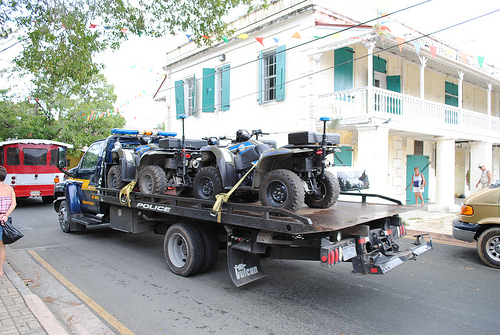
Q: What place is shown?
A: It is a road.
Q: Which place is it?
A: It is a road.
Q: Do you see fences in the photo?
A: No, there are no fences.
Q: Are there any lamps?
A: No, there are no lamps.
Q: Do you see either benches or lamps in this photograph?
A: No, there are no lamps or benches.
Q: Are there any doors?
A: Yes, there is a door.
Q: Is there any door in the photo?
A: Yes, there is a door.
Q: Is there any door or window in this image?
A: Yes, there is a door.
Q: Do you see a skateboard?
A: No, there are no skateboards.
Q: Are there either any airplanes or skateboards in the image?
A: No, there are no skateboards or airplanes.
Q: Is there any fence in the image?
A: No, there are no fences.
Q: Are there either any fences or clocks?
A: No, there are no fences or clocks.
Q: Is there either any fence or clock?
A: No, there are no fences or clocks.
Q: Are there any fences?
A: No, there are no fences.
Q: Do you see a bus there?
A: Yes, there is a bus.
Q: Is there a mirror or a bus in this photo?
A: Yes, there is a bus.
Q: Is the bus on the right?
A: No, the bus is on the left of the image.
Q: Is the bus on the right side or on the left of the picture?
A: The bus is on the left of the image.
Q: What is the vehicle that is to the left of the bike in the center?
A: The vehicle is a bus.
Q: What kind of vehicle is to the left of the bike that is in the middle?
A: The vehicle is a bus.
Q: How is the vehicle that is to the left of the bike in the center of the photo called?
A: The vehicle is a bus.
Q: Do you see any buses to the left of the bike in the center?
A: Yes, there is a bus to the left of the bike.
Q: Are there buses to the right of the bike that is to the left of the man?
A: No, the bus is to the left of the bike.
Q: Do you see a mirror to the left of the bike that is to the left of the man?
A: No, there is a bus to the left of the bike.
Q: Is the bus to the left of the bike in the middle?
A: Yes, the bus is to the left of the bike.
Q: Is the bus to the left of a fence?
A: No, the bus is to the left of the bike.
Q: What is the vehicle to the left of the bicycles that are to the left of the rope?
A: The vehicle is a bus.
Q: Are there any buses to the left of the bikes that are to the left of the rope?
A: Yes, there is a bus to the left of the bikes.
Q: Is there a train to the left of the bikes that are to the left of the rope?
A: No, there is a bus to the left of the bicycles.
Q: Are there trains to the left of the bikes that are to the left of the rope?
A: No, there is a bus to the left of the bicycles.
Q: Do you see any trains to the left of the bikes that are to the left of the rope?
A: No, there is a bus to the left of the bicycles.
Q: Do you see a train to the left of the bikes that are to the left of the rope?
A: No, there is a bus to the left of the bicycles.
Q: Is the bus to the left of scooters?
A: No, the bus is to the left of the bicycles.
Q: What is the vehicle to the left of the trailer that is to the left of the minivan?
A: The vehicle is a bus.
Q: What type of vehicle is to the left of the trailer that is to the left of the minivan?
A: The vehicle is a bus.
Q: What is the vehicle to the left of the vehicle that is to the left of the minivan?
A: The vehicle is a bus.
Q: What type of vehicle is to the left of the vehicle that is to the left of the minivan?
A: The vehicle is a bus.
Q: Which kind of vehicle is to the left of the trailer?
A: The vehicle is a bus.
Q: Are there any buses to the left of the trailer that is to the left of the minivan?
A: Yes, there is a bus to the left of the trailer.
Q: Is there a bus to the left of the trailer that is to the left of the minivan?
A: Yes, there is a bus to the left of the trailer.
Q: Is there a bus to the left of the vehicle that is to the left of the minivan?
A: Yes, there is a bus to the left of the trailer.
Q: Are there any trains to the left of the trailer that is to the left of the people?
A: No, there is a bus to the left of the trailer.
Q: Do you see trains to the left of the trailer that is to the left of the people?
A: No, there is a bus to the left of the trailer.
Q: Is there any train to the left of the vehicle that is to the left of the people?
A: No, there is a bus to the left of the trailer.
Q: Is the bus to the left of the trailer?
A: Yes, the bus is to the left of the trailer.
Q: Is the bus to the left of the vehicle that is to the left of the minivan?
A: Yes, the bus is to the left of the trailer.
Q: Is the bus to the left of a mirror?
A: No, the bus is to the left of the trailer.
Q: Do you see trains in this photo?
A: No, there are no trains.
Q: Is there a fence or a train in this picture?
A: No, there are no trains or fences.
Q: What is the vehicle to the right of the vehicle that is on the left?
A: The vehicle is a trailer.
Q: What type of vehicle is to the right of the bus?
A: The vehicle is a trailer.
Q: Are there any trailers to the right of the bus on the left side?
A: Yes, there is a trailer to the right of the bus.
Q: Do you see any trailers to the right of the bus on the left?
A: Yes, there is a trailer to the right of the bus.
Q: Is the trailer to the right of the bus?
A: Yes, the trailer is to the right of the bus.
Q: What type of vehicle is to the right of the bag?
A: The vehicle is a trailer.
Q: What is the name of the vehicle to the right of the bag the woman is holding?
A: The vehicle is a trailer.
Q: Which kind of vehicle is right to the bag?
A: The vehicle is a trailer.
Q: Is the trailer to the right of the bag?
A: Yes, the trailer is to the right of the bag.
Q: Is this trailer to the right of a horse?
A: No, the trailer is to the right of the bag.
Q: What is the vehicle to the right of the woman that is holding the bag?
A: The vehicle is a trailer.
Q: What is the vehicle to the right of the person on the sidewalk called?
A: The vehicle is a trailer.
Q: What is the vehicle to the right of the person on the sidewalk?
A: The vehicle is a trailer.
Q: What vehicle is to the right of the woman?
A: The vehicle is a trailer.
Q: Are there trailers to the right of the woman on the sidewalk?
A: Yes, there is a trailer to the right of the woman.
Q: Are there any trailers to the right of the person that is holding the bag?
A: Yes, there is a trailer to the right of the woman.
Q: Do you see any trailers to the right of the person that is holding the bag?
A: Yes, there is a trailer to the right of the woman.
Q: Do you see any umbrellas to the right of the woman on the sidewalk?
A: No, there is a trailer to the right of the woman.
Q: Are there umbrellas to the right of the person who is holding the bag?
A: No, there is a trailer to the right of the woman.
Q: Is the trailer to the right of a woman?
A: Yes, the trailer is to the right of a woman.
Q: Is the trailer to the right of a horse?
A: No, the trailer is to the right of a woman.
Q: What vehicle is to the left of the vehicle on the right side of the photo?
A: The vehicle is a trailer.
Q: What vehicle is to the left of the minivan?
A: The vehicle is a trailer.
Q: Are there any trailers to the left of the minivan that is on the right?
A: Yes, there is a trailer to the left of the minivan.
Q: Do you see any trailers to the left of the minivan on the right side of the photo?
A: Yes, there is a trailer to the left of the minivan.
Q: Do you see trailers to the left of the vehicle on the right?
A: Yes, there is a trailer to the left of the minivan.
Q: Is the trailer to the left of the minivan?
A: Yes, the trailer is to the left of the minivan.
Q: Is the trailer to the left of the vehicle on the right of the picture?
A: Yes, the trailer is to the left of the minivan.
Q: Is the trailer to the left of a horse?
A: No, the trailer is to the left of the minivan.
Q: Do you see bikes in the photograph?
A: Yes, there are bikes.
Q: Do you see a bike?
A: Yes, there are bikes.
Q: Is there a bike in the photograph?
A: Yes, there are bikes.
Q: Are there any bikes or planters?
A: Yes, there are bikes.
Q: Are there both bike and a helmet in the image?
A: No, there are bikes but no helmets.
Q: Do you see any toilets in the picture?
A: No, there are no toilets.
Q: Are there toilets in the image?
A: No, there are no toilets.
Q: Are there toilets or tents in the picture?
A: No, there are no toilets or tents.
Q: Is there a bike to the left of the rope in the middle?
A: Yes, there are bikes to the left of the rope.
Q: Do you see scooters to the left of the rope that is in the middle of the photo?
A: No, there are bikes to the left of the rope.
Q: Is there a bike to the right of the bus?
A: Yes, there are bikes to the right of the bus.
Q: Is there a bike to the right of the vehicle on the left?
A: Yes, there are bikes to the right of the bus.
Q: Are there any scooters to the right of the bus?
A: No, there are bikes to the right of the bus.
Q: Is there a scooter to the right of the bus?
A: No, there are bikes to the right of the bus.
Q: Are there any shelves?
A: No, there are no shelves.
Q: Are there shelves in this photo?
A: No, there are no shelves.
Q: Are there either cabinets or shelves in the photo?
A: No, there are no shelves or cabinets.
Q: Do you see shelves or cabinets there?
A: No, there are no shelves or cabinets.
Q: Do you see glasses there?
A: No, there are no glasses.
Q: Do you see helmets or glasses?
A: No, there are no glasses or helmets.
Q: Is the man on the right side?
A: Yes, the man is on the right of the image.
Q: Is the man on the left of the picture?
A: No, the man is on the right of the image.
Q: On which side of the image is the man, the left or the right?
A: The man is on the right of the image.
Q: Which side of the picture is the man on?
A: The man is on the right of the image.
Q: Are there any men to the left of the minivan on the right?
A: Yes, there is a man to the left of the minivan.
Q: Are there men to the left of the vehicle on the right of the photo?
A: Yes, there is a man to the left of the minivan.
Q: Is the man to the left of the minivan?
A: Yes, the man is to the left of the minivan.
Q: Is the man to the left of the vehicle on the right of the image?
A: Yes, the man is to the left of the minivan.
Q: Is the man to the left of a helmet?
A: No, the man is to the left of the minivan.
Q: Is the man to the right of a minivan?
A: No, the man is to the left of a minivan.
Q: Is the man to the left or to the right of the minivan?
A: The man is to the left of the minivan.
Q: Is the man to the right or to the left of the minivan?
A: The man is to the left of the minivan.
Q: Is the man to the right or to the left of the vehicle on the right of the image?
A: The man is to the left of the minivan.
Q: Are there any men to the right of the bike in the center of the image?
A: Yes, there is a man to the right of the bike.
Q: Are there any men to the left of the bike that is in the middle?
A: No, the man is to the right of the bike.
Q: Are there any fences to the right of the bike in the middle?
A: No, there is a man to the right of the bike.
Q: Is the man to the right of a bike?
A: Yes, the man is to the right of a bike.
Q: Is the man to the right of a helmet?
A: No, the man is to the right of a bike.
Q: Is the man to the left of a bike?
A: No, the man is to the right of a bike.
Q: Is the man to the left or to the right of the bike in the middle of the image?
A: The man is to the right of the bike.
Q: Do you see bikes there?
A: Yes, there is a bike.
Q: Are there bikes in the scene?
A: Yes, there is a bike.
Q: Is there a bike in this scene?
A: Yes, there is a bike.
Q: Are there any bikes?
A: Yes, there is a bike.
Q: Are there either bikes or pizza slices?
A: Yes, there is a bike.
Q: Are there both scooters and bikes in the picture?
A: No, there is a bike but no scooters.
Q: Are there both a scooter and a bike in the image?
A: No, there is a bike but no scooters.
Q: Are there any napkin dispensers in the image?
A: No, there are no napkin dispensers.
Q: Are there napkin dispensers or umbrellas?
A: No, there are no napkin dispensers or umbrellas.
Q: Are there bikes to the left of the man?
A: Yes, there is a bike to the left of the man.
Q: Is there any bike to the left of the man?
A: Yes, there is a bike to the left of the man.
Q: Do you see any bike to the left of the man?
A: Yes, there is a bike to the left of the man.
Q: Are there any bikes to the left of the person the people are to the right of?
A: Yes, there is a bike to the left of the man.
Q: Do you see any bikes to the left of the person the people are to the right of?
A: Yes, there is a bike to the left of the man.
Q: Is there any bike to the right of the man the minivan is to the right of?
A: No, the bike is to the left of the man.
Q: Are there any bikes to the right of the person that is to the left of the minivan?
A: No, the bike is to the left of the man.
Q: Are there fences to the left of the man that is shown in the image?
A: No, there is a bike to the left of the man.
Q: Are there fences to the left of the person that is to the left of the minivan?
A: No, there is a bike to the left of the man.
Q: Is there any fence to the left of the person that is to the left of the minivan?
A: No, there is a bike to the left of the man.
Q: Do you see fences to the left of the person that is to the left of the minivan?
A: No, there is a bike to the left of the man.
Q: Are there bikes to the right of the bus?
A: Yes, there is a bike to the right of the bus.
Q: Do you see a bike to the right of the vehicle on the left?
A: Yes, there is a bike to the right of the bus.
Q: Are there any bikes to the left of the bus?
A: No, the bike is to the right of the bus.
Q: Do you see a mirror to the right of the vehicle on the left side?
A: No, there is a bike to the right of the bus.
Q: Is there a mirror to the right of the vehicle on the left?
A: No, there is a bike to the right of the bus.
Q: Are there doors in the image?
A: Yes, there are doors.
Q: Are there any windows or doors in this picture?
A: Yes, there are doors.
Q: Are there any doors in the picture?
A: Yes, there are doors.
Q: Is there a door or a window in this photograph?
A: Yes, there are doors.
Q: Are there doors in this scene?
A: Yes, there are doors.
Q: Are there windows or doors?
A: Yes, there are doors.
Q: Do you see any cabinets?
A: No, there are no cabinets.